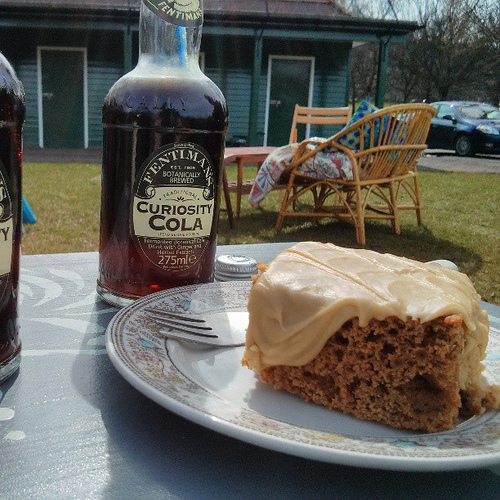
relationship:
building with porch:
[0, 8, 422, 145] [19, 146, 104, 166]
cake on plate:
[241, 240, 500, 431] [144, 355, 284, 457]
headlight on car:
[470, 121, 498, 138] [433, 94, 490, 149]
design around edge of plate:
[121, 329, 302, 416] [88, 283, 492, 460]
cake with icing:
[241, 240, 484, 421] [243, 238, 484, 365]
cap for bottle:
[214, 251, 259, 281] [96, 3, 228, 306]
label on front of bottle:
[133, 146, 218, 278] [96, 3, 228, 306]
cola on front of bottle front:
[148, 215, 203, 235] [112, 12, 227, 297]